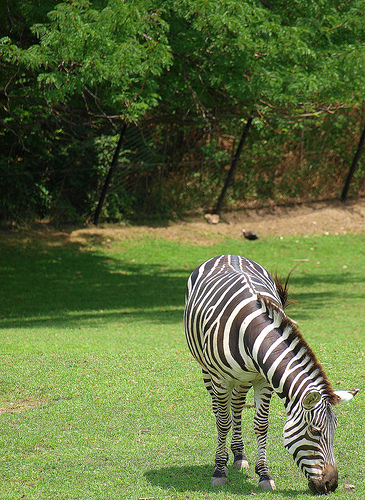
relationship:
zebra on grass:
[182, 255, 359, 492] [1, 212, 363, 499]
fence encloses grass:
[3, 108, 363, 232] [1, 212, 363, 499]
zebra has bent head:
[182, 255, 359, 492] [282, 389, 360, 493]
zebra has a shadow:
[182, 255, 359, 492] [143, 459, 298, 497]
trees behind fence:
[1, 5, 358, 222] [3, 108, 363, 232]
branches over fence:
[64, 85, 322, 147] [3, 108, 363, 232]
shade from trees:
[1, 216, 364, 321] [1, 5, 358, 222]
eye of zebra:
[308, 419, 328, 442] [182, 255, 359, 492]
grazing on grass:
[276, 450, 364, 499] [1, 212, 363, 499]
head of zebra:
[282, 389, 360, 493] [182, 255, 359, 492]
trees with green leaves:
[1, 5, 358, 222] [36, 22, 332, 64]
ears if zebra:
[297, 386, 361, 413] [182, 255, 359, 492]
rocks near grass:
[206, 207, 263, 243] [1, 212, 363, 499]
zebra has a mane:
[182, 255, 359, 492] [253, 288, 335, 398]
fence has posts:
[3, 108, 363, 232] [92, 117, 257, 233]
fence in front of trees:
[3, 108, 363, 232] [1, 5, 358, 222]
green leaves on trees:
[36, 22, 332, 64] [1, 5, 358, 222]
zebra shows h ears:
[182, 255, 359, 492] [297, 386, 361, 413]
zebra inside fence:
[182, 255, 359, 492] [3, 108, 363, 232]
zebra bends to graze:
[182, 255, 359, 492] [299, 456, 343, 499]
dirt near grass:
[79, 199, 363, 239] [1, 212, 363, 499]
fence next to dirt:
[3, 108, 363, 232] [79, 199, 363, 239]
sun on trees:
[22, 0, 327, 67] [1, 5, 358, 222]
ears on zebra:
[297, 386, 361, 413] [182, 255, 359, 492]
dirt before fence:
[79, 199, 363, 239] [3, 108, 363, 232]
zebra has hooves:
[182, 255, 359, 492] [205, 453, 280, 493]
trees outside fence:
[1, 5, 358, 222] [3, 108, 363, 232]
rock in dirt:
[241, 221, 255, 244] [79, 199, 363, 239]